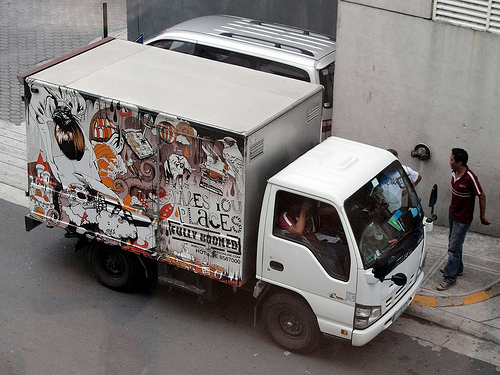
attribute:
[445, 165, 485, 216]
shirt — red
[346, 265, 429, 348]
bumper — white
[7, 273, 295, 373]
road — side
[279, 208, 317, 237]
shirt — white, maroon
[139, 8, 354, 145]
van — white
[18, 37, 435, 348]
truck — delivery, white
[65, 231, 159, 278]
tire — black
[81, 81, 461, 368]
truck — white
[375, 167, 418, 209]
shirt — white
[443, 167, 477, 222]
shirt — man's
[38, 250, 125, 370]
street — city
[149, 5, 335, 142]
van — silver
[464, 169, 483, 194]
stripe — white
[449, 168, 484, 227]
shirt — maroon, white